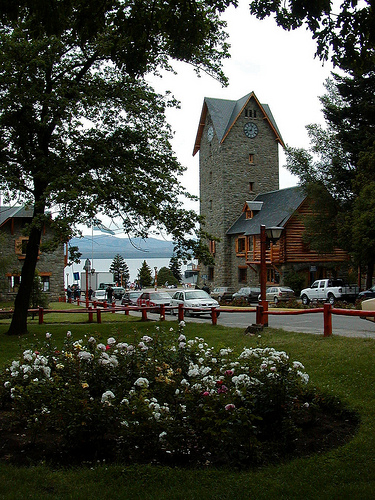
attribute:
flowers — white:
[9, 318, 330, 483]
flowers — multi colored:
[224, 403, 235, 411]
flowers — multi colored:
[236, 372, 247, 382]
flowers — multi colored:
[295, 369, 311, 386]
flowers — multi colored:
[98, 388, 115, 403]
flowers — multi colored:
[140, 335, 150, 343]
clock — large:
[243, 122, 258, 139]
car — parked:
[169, 289, 219, 319]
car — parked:
[138, 285, 174, 317]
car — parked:
[113, 287, 145, 310]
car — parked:
[93, 287, 110, 301]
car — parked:
[257, 285, 298, 305]